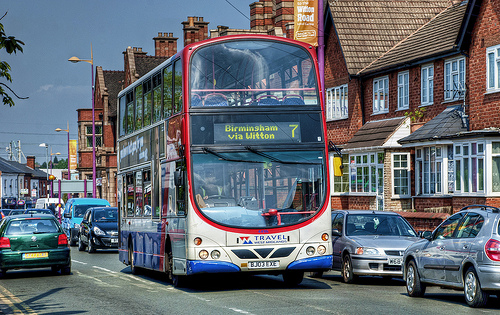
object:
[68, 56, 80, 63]
streetlight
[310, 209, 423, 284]
car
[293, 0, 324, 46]
sign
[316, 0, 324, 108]
pole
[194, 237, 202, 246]
headlight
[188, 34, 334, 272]
bus front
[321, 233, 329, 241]
left headlight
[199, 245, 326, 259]
headlights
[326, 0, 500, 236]
building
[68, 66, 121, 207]
building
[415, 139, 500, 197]
window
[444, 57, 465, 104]
window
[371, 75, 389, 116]
window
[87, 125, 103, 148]
window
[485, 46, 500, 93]
window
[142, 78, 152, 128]
window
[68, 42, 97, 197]
pole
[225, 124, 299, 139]
sign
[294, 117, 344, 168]
ground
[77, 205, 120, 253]
car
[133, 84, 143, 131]
window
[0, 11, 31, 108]
branches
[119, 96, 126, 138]
window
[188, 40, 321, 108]
window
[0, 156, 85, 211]
building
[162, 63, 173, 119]
window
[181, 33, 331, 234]
border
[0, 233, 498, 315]
street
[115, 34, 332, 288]
bus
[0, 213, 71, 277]
car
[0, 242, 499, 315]
road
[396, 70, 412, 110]
correct window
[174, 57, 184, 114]
window